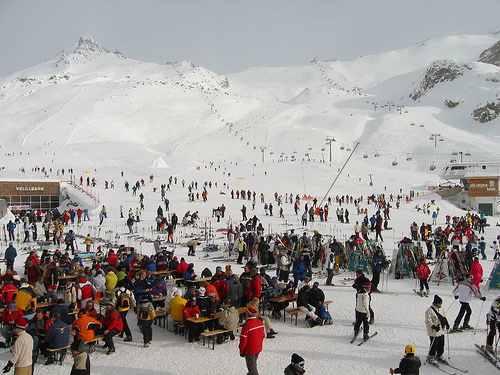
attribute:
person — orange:
[65, 306, 102, 361]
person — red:
[237, 305, 265, 372]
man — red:
[236, 305, 270, 373]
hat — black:
[429, 293, 442, 303]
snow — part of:
[7, 44, 496, 374]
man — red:
[239, 308, 264, 373]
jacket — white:
[354, 281, 369, 340]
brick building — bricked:
[2, 176, 62, 222]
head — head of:
[293, 354, 304, 371]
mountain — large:
[23, 22, 211, 143]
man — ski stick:
[422, 287, 459, 368]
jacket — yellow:
[167, 295, 187, 322]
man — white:
[421, 294, 450, 359]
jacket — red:
[235, 313, 278, 353]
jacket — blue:
[36, 311, 76, 358]